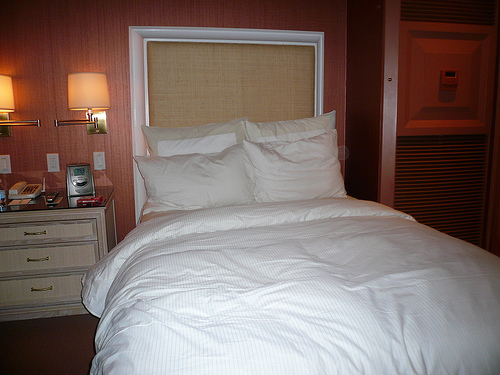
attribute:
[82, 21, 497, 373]
bed — made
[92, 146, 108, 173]
light switch — white 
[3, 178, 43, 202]
telephone — white 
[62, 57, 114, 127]
fire hydrant — illuminated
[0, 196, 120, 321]
dresser — white 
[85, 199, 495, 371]
comforter — white, wrinkled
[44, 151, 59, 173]
socket — electrical